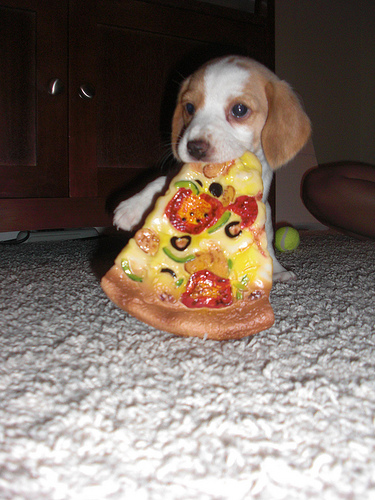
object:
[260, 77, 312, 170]
ear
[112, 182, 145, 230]
paw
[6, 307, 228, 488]
ground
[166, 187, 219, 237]
tomato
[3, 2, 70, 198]
door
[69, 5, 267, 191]
door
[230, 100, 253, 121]
eye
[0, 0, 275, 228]
wooden cabinet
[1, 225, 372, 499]
carpet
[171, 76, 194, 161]
ear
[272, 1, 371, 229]
wall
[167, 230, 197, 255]
olive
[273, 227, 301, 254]
ball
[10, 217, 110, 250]
electricity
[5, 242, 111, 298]
ground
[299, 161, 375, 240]
folded leg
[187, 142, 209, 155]
nose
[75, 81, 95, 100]
knob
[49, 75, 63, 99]
knob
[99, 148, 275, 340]
pizza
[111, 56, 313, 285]
puppy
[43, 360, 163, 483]
ground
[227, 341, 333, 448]
ground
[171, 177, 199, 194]
green pepper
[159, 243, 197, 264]
green pepper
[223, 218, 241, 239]
olive slice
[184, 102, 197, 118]
eyes